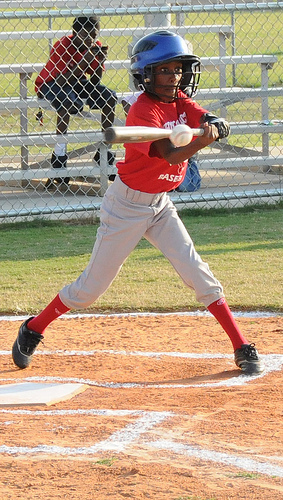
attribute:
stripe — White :
[0, 345, 280, 368]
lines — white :
[170, 434, 277, 496]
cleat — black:
[232, 343, 261, 371]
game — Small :
[89, 43, 114, 62]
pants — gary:
[71, 166, 232, 326]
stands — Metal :
[1, 20, 279, 188]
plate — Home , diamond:
[29, 369, 93, 408]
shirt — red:
[113, 84, 212, 196]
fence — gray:
[0, 0, 282, 222]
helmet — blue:
[128, 22, 204, 93]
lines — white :
[5, 308, 281, 479]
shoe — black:
[234, 341, 264, 374]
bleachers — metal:
[208, 38, 280, 87]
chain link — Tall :
[213, 20, 270, 83]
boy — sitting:
[38, 16, 122, 191]